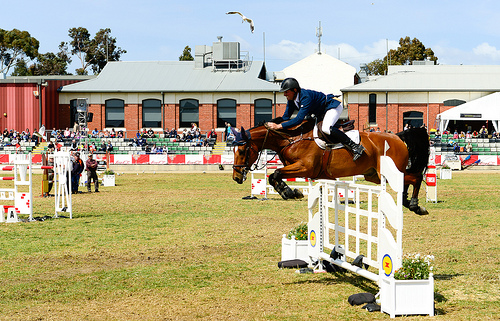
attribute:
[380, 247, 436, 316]
box — planter, white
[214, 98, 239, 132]
window — large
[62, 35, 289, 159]
building — brick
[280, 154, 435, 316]
fence — white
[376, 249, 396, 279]
logo — yellow, blue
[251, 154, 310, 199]
fence —  white , for jumping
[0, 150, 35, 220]
fence — white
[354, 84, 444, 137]
building — large, brick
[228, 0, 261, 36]
seabird — white, black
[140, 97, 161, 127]
window — brick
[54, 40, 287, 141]
building — large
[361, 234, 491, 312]
flowers — white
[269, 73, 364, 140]
male —   jockey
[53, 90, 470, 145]
building — large, brick